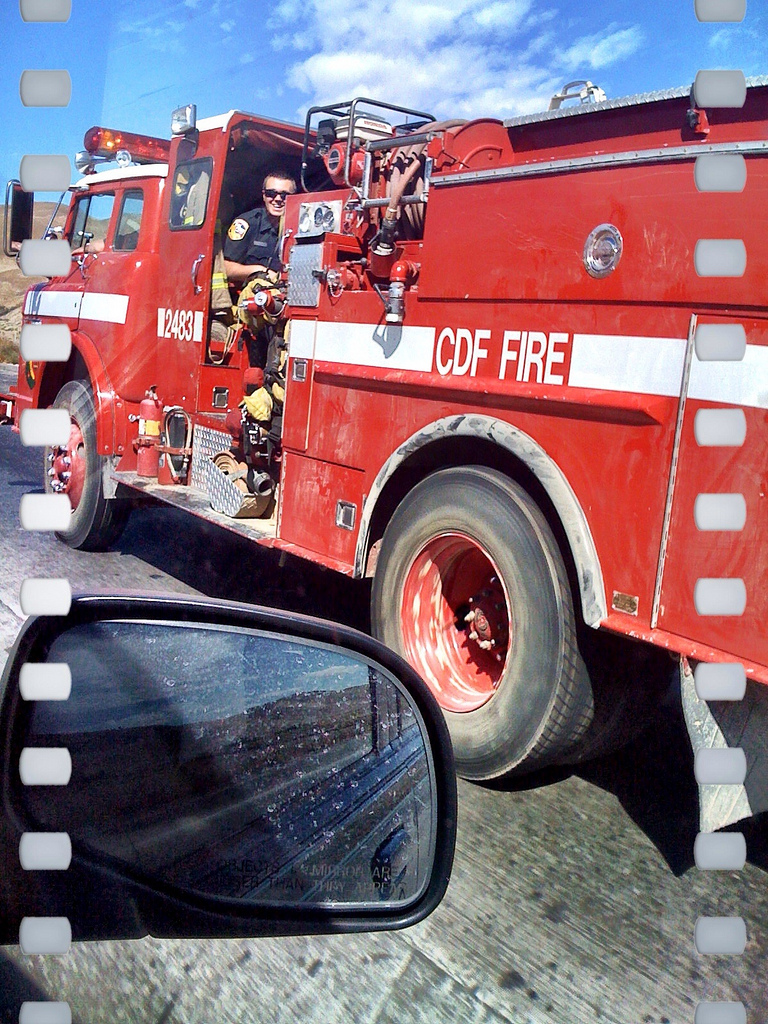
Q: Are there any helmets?
A: No, there are no helmets.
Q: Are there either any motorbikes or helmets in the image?
A: No, there are no helmets or motorbikes.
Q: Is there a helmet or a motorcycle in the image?
A: No, there are no helmets or motorcycles.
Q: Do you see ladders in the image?
A: No, there are no ladders.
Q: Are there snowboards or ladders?
A: No, there are no ladders or snowboards.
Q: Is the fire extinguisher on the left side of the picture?
A: Yes, the fire extinguisher is on the left of the image.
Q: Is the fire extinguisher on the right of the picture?
A: No, the fire extinguisher is on the left of the image.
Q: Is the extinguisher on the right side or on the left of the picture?
A: The extinguisher is on the left of the image.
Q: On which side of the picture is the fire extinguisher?
A: The fire extinguisher is on the left of the image.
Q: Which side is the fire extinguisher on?
A: The fire extinguisher is on the left of the image.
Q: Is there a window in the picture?
A: Yes, there are windows.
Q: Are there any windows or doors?
A: Yes, there are windows.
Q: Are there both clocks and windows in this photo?
A: No, there are windows but no clocks.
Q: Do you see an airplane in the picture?
A: No, there are no airplanes.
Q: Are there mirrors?
A: Yes, there is a mirror.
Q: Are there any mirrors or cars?
A: Yes, there is a mirror.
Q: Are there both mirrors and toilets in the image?
A: No, there is a mirror but no toilets.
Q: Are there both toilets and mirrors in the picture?
A: No, there is a mirror but no toilets.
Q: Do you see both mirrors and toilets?
A: No, there is a mirror but no toilets.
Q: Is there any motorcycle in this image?
A: No, there are no motorcycles.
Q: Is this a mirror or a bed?
A: This is a mirror.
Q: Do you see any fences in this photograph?
A: No, there are no fences.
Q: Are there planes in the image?
A: No, there are no planes.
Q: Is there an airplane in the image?
A: No, there are no airplanes.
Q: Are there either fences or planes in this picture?
A: No, there are no planes or fences.